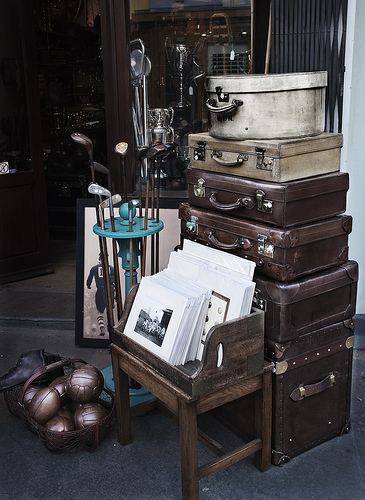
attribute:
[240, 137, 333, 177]
trunk — brown, leather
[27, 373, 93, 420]
balls — copper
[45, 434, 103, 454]
basket — red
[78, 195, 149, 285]
holder — blue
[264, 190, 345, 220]
suitcase — stacked, light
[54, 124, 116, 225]
golf club — brown, antique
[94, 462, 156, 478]
carpet — blue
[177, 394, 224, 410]
bench — print, antique, brown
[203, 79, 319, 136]
luggage — old fashioned, stacked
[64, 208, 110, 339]
picture — antique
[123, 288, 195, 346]
pictures — stacked, black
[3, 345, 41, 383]
shoes — black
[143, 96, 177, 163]
trophy — silver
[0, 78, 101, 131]
gate — black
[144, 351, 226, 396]
crate — brown, wood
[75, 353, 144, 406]
stand — turquoise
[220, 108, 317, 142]
box — round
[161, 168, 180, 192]
case — glass